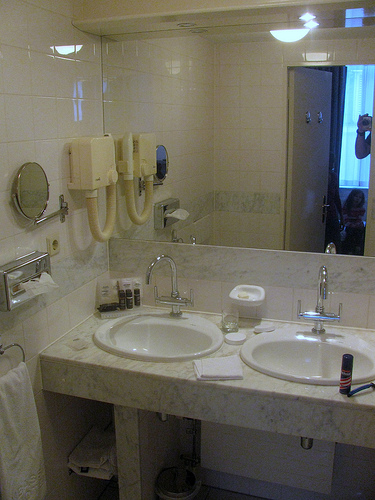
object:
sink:
[91, 312, 224, 363]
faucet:
[295, 265, 341, 336]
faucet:
[143, 254, 194, 319]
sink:
[238, 325, 375, 386]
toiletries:
[131, 287, 141, 309]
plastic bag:
[154, 463, 201, 499]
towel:
[0, 360, 62, 499]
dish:
[227, 284, 265, 307]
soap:
[237, 292, 250, 298]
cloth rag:
[191, 353, 245, 381]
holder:
[0, 251, 53, 314]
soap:
[251, 322, 275, 335]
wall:
[97, 18, 374, 333]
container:
[224, 330, 248, 343]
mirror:
[99, 17, 374, 256]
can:
[152, 465, 202, 499]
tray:
[99, 305, 146, 319]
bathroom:
[0, 1, 374, 499]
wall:
[0, 1, 110, 499]